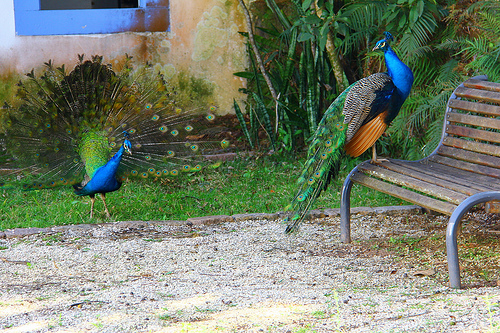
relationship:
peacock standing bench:
[273, 29, 420, 249] [326, 84, 477, 284]